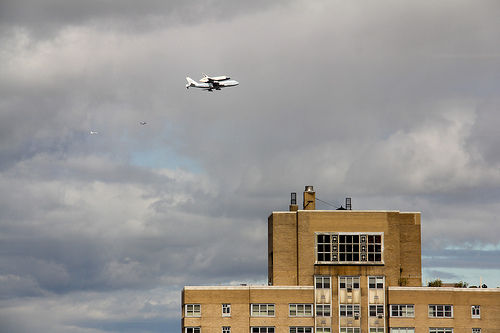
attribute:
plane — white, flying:
[185, 76, 238, 93]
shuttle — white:
[199, 74, 230, 83]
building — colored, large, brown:
[181, 185, 500, 332]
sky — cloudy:
[1, 0, 498, 332]